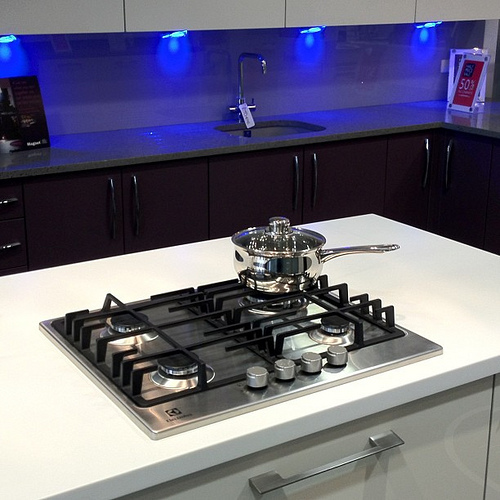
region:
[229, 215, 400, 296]
shiny new saucepan on a stove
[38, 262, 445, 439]
four gas burners on a stove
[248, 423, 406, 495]
door handle of the oven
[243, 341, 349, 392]
row of four knobs on the stove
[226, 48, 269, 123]
new faucet with a tag on it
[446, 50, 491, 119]
50% off sign on the counter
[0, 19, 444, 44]
blue lights on the bottom of the cabinets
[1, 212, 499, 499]
white topped kitchen island with a stove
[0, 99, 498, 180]
gray speckled countertop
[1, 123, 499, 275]
dark brown cabinets under the counter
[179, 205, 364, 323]
a pan on the stove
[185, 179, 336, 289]
a pan on the stove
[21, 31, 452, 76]
kitchen lights are blue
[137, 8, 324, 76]
kitchen lights are blue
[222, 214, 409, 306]
an extremely shiny silvertone metal pot in an extraordinarily clean model kitchen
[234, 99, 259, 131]
pricetag on unusually fashioned faucet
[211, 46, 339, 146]
an unusually fashioned faucet leading to an attractive, almost cavepit-like primer colour sink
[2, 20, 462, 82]
pretty glowing blue track, slightly recessed, lighting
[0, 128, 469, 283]
dark cabinets, long silvertone handles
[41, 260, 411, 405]
exceptionally fashionable black squared burner grates set in white countertop of island kitchen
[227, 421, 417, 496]
again, contemporary fashionable handle, probably for euphemistic oven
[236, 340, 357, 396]
four round burner dials, poking upward, looking like brushed silvertone marshmallows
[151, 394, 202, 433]
maker's mark of stovetop, illegible here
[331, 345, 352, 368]
knob on the stove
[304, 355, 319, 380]
knob on the stove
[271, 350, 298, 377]
knob on the stove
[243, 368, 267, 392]
knob on the stove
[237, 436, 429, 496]
handle on the oven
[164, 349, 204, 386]
eye on the stove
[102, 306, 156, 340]
eye on the stove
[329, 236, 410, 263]
handle of the pot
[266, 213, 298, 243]
top of the lid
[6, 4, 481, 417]
a kitchen on display in a showroom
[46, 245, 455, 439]
a gas stove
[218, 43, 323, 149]
the sink of a kitchen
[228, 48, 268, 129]
the faucet of a sink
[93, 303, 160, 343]
a burner on a gas stove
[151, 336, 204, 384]
a burner on a gas stove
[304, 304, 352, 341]
a burner on a gas stove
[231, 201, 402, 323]
a pot on a gas stove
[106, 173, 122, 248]
the handle of a cabinet door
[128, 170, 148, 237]
the handle of a cabinet door